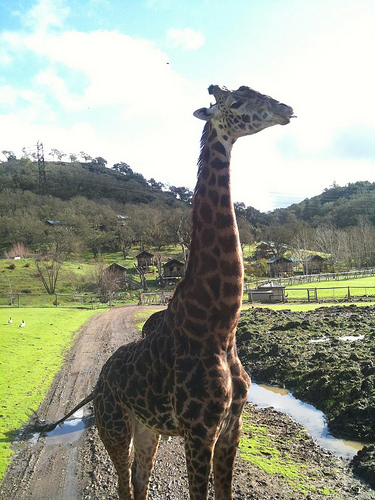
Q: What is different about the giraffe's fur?
A: Mosaic patches.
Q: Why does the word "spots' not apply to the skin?
A: Irregular splotches.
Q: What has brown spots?
A: Giraffe.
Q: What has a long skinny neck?
A: Giraffe.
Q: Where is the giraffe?
A: On the path.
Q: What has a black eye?
A: Giraffe.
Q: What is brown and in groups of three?
A: Huts.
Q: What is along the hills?
A: Trees.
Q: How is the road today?
A: Muddy.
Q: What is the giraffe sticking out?
A: Tongue.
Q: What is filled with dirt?
A: Road.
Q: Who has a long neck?
A: Giraffe.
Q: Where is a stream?
A: On the right.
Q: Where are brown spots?
A: On the giraffe.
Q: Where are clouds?
A: In the sky.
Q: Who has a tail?
A: The giraffe.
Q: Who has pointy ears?
A: The giraffe.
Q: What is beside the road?
A: A ditch.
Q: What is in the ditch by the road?
A: Water.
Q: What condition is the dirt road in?
A: Muddy.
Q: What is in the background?
A: Mountains.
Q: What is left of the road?
A: Grass.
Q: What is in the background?
A: A house and outbuildings.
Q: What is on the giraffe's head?
A: Horns.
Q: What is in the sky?
A: Clouds.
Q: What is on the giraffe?
A: Fur.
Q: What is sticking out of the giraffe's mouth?
A: Tongue.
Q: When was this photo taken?
A: During the daytime.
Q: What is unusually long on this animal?
A: Neck.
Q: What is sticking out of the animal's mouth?
A: The tongue.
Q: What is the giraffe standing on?
A: A gravel road.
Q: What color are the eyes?
A: Brown.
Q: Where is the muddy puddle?
A: To the left of the giraffe.